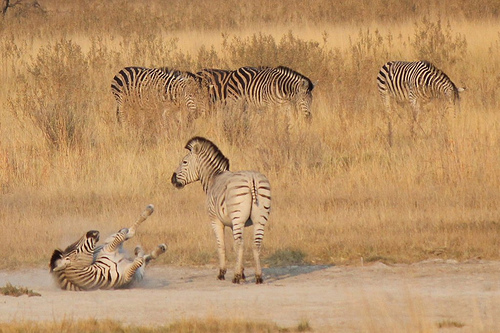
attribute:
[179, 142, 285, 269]
zebra — black, white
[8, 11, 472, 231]
ground — tan, brown, daytime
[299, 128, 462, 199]
grass — dry, tall, yellow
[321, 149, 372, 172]
graass — green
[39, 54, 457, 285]
zebra — six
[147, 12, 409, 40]
grass — brown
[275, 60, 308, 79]
hairs — short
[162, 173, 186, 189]
zebra mouth — blackcolor, black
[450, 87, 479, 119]
zebrashead — down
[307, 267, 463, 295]
path — tan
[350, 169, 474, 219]
grassland — yellow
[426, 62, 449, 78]
mane — black, white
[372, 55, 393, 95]
zebrarear — black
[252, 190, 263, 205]
tail — black